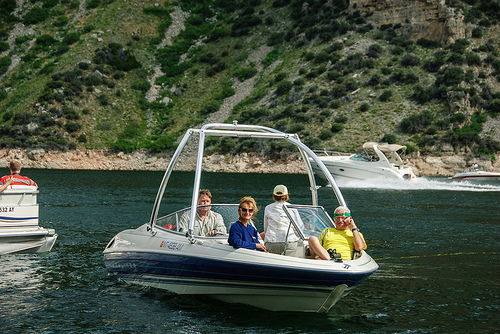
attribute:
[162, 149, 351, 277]
people — enjoyinng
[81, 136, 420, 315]
boat — creating, small, power, motor, fast, background, create, third, four, white, making wave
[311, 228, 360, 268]
shirt — yellow, blue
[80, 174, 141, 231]
water — calm, green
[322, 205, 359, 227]
foilage — green, wearing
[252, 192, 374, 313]
man — sitting, wearing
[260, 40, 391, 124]
hill — covered, background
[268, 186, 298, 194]
cap — baseball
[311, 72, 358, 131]
bush — small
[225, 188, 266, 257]
woman — facing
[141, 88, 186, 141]
grass — green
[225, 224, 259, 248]
top — blue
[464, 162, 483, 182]
shore — rocky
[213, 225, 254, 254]
bar — gray